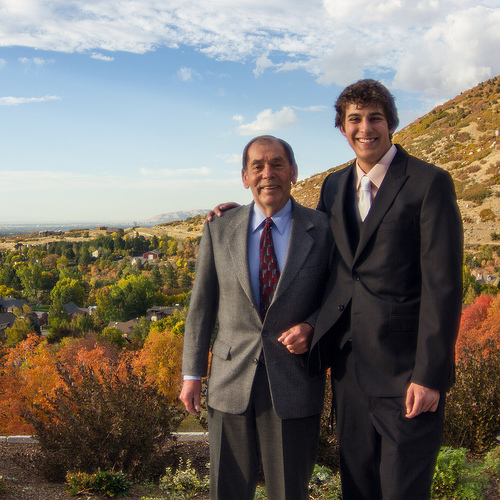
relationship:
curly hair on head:
[332, 75, 403, 127] [330, 73, 401, 161]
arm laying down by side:
[416, 184, 459, 437] [398, 264, 418, 379]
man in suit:
[306, 76, 466, 498] [319, 171, 457, 491]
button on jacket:
[333, 299, 344, 319] [188, 197, 319, 374]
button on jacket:
[349, 271, 365, 283] [188, 197, 319, 374]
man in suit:
[178, 133, 332, 498] [181, 199, 326, 499]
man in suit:
[306, 77, 466, 498] [309, 151, 467, 496]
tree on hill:
[132, 322, 182, 401] [5, 372, 211, 499]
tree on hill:
[50, 333, 118, 416] [5, 372, 211, 499]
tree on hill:
[0, 331, 74, 435] [5, 372, 211, 499]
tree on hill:
[452, 293, 498, 369] [5, 372, 211, 499]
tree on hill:
[93, 286, 122, 320] [0, 283, 498, 493]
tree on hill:
[0, 331, 74, 435] [0, 283, 498, 493]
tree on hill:
[50, 333, 118, 416] [0, 283, 498, 493]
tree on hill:
[132, 322, 182, 401] [0, 283, 498, 493]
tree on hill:
[449, 293, 497, 468] [0, 283, 498, 493]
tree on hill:
[455, 289, 499, 369] [9, 264, 496, 496]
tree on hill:
[132, 322, 182, 401] [9, 264, 496, 496]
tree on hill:
[24, 326, 144, 422] [9, 264, 496, 496]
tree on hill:
[0, 331, 74, 435] [9, 264, 496, 496]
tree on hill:
[0, 331, 74, 435] [17, 307, 174, 494]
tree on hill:
[50, 333, 118, 416] [17, 307, 174, 494]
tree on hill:
[132, 322, 182, 401] [17, 307, 174, 494]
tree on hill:
[455, 289, 499, 369] [0, 283, 498, 493]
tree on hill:
[126, 321, 208, 427] [0, 283, 498, 493]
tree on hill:
[54, 341, 140, 405] [0, 283, 498, 493]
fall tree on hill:
[454, 292, 499, 364] [0, 283, 498, 493]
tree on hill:
[50, 333, 141, 416] [0, 283, 498, 493]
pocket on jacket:
[208, 341, 233, 386] [178, 205, 330, 499]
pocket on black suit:
[389, 304, 421, 343] [308, 143, 465, 400]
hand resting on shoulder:
[206, 202, 237, 217] [201, 202, 248, 221]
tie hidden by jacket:
[351, 171, 383, 220] [300, 144, 473, 411]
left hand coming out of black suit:
[402, 380, 445, 422] [318, 162, 447, 373]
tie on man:
[257, 212, 281, 312] [176, 130, 336, 497]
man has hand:
[210, 122, 330, 462] [270, 308, 315, 358]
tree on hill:
[26, 357, 189, 493] [2, 74, 498, 497]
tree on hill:
[2, 343, 199, 493] [3, 422, 498, 499]